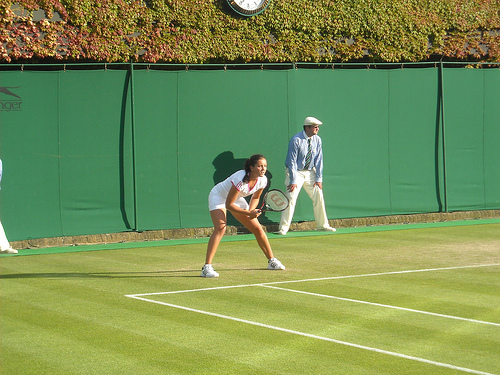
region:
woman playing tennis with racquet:
[186, 152, 293, 278]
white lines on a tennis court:
[231, 295, 380, 350]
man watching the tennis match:
[280, 111, 346, 241]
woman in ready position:
[188, 147, 293, 284]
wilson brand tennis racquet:
[242, 185, 295, 230]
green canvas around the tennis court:
[63, 102, 213, 184]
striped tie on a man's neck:
[304, 137, 316, 169]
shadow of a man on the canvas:
[193, 128, 239, 174]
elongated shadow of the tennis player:
[9, 256, 186, 303]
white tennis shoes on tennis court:
[194, 263, 221, 285]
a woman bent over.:
[196, 143, 288, 278]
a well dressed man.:
[275, 90, 356, 240]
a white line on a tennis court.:
[255, 283, 496, 328]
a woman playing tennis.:
[195, 140, 286, 280]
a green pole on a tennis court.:
[125, 55, 148, 236]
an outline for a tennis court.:
[117, 255, 497, 373]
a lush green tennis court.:
[2, 222, 493, 372]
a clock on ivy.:
[215, 0, 276, 13]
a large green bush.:
[2, 0, 497, 76]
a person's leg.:
[0, 218, 28, 253]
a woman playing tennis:
[176, 144, 301, 283]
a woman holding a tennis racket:
[178, 140, 295, 282]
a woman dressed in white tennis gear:
[182, 135, 297, 286]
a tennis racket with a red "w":
[245, 183, 295, 230]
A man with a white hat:
[271, 106, 341, 241]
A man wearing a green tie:
[266, 107, 357, 239]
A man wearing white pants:
[269, 100, 344, 244]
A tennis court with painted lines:
[103, 258, 498, 372]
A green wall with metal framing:
[8, 66, 160, 231]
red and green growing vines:
[46, 4, 218, 65]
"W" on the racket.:
[261, 186, 290, 219]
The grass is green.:
[10, 280, 112, 371]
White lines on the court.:
[143, 286, 435, 359]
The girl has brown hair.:
[238, 152, 273, 179]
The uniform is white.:
[206, 166, 263, 226]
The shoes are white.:
[196, 253, 289, 279]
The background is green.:
[31, 83, 125, 220]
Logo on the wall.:
[1, 78, 25, 117]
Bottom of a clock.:
[226, 1, 276, 24]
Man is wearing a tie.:
[305, 137, 317, 169]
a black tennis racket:
[253, 186, 288, 224]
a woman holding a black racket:
[199, 153, 293, 279]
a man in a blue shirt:
[273, 114, 334, 233]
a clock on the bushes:
[219, 0, 276, 20]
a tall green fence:
[0, 59, 499, 244]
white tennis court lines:
[125, 263, 497, 373]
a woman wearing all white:
[199, 151, 287, 278]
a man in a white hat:
[271, 114, 338, 234]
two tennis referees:
[0, 114, 339, 256]